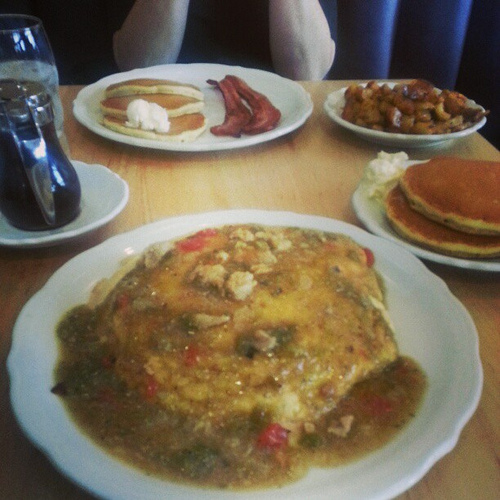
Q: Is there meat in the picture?
A: Yes, there is meat.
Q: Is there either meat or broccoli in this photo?
A: Yes, there is meat.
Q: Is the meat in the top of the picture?
A: Yes, the meat is in the top of the image.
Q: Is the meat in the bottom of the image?
A: No, the meat is in the top of the image.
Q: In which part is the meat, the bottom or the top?
A: The meat is in the top of the image.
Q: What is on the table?
A: The meat is on the table.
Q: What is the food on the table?
A: The food is meat.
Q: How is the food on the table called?
A: The food is meat.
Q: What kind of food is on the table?
A: The food is meat.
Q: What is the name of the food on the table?
A: The food is meat.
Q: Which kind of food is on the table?
A: The food is meat.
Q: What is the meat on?
A: The meat is on the table.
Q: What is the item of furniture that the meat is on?
A: The piece of furniture is a table.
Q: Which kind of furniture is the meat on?
A: The meat is on the table.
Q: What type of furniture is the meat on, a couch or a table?
A: The meat is on a table.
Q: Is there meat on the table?
A: Yes, there is meat on the table.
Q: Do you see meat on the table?
A: Yes, there is meat on the table.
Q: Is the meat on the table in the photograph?
A: Yes, the meat is on the table.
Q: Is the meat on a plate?
A: No, the meat is on the table.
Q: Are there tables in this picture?
A: Yes, there is a table.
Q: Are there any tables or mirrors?
A: Yes, there is a table.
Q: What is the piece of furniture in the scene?
A: The piece of furniture is a table.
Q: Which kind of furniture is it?
A: The piece of furniture is a table.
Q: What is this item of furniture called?
A: That is a table.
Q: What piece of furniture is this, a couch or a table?
A: That is a table.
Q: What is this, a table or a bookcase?
A: This is a table.